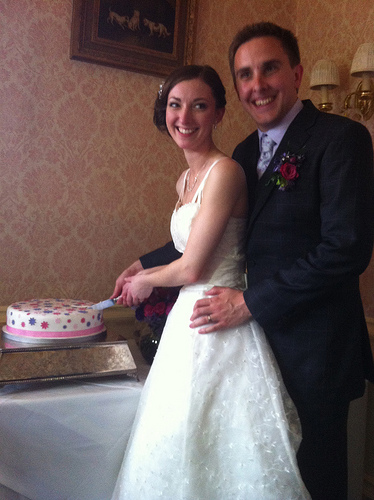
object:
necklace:
[186, 152, 211, 193]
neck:
[183, 138, 218, 170]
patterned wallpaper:
[1, 0, 190, 305]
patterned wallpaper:
[193, 0, 372, 157]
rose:
[280, 162, 299, 181]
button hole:
[286, 165, 292, 173]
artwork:
[68, 0, 199, 81]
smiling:
[170, 122, 199, 136]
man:
[110, 21, 374, 500]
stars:
[40, 320, 49, 330]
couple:
[113, 20, 374, 498]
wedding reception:
[0, 0, 374, 498]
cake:
[2, 298, 107, 341]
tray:
[0, 339, 137, 384]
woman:
[113, 64, 309, 498]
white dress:
[112, 157, 311, 499]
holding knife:
[91, 259, 152, 310]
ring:
[207, 315, 211, 323]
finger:
[189, 312, 219, 329]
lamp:
[307, 59, 339, 113]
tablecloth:
[0, 368, 141, 496]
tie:
[257, 136, 276, 179]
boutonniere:
[264, 149, 305, 192]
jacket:
[136, 97, 374, 406]